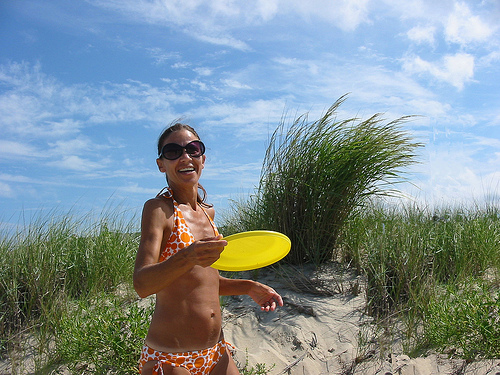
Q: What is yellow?
A: A frisbee.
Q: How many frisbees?
A: One.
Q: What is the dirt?
A: Sand.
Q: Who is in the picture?
A: A lady.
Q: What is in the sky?
A: Clouds.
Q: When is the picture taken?
A: Daytime.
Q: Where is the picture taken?
A: On a beach.